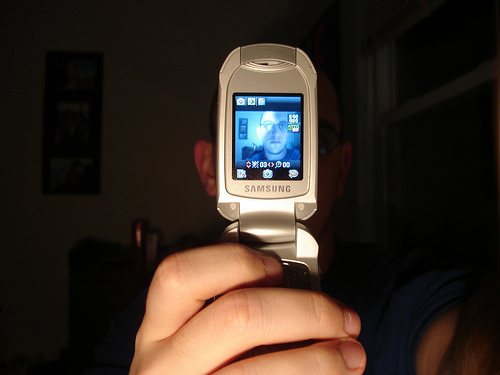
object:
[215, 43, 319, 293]
cell phone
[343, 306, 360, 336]
nails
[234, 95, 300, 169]
picture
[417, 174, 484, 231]
ground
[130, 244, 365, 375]
hand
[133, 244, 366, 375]
knuckle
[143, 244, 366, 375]
finger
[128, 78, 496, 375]
man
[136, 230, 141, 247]
light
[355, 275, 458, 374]
sleeve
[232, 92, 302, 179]
screen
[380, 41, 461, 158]
frame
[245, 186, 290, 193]
logo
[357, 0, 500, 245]
window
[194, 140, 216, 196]
ears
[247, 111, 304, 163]
owner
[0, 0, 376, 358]
cabinet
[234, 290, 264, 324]
lines